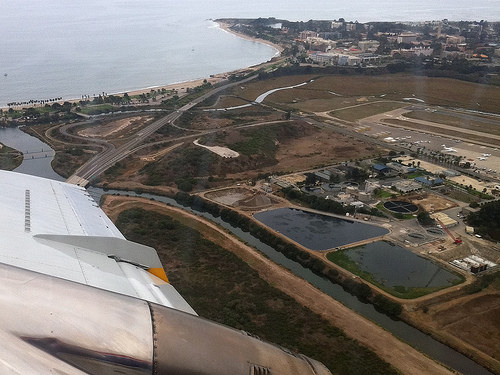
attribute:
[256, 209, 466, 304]
water — large body, calm, blue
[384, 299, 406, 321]
tree — green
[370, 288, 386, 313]
tree — green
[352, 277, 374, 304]
tree — green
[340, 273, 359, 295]
tree — green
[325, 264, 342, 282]
tree — green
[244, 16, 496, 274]
city — small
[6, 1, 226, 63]
water — calm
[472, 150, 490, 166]
airplane — white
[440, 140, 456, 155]
airplane — white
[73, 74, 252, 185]
road — asphalt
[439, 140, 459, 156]
airplane — parked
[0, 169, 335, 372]
plane — yellow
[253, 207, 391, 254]
pool — water, large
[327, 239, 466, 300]
pond — rectangular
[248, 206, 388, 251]
pond — rectangular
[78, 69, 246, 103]
beach — Narrow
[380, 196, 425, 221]
landing pad — black, white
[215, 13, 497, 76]
city — Urbanized 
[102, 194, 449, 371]
path — dirt